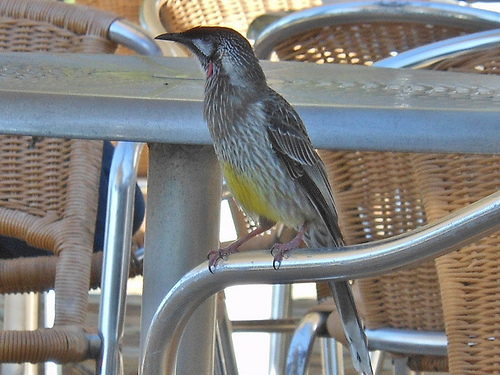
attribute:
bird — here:
[147, 23, 376, 373]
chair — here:
[137, 192, 499, 372]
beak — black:
[155, 29, 196, 50]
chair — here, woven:
[1, 2, 133, 374]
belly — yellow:
[213, 157, 292, 225]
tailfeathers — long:
[312, 244, 383, 371]